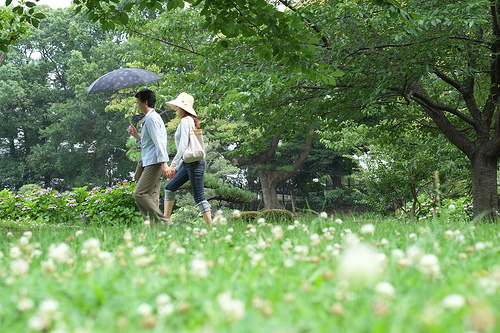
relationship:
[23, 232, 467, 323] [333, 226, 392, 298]
grass has flowers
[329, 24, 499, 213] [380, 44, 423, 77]
tree has leaves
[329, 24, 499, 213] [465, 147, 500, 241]
tree has trunk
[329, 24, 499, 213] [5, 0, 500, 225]
tree in background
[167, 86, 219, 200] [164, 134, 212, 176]
woman has arm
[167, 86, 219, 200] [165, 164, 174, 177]
woman has hand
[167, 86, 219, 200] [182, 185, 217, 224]
woman has leg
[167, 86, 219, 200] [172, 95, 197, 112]
woman has hat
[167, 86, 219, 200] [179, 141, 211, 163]
woman carrying purse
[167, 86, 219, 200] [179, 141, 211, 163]
woman has purse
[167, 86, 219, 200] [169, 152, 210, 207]
woman has jeans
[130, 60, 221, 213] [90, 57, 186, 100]
people with umbrella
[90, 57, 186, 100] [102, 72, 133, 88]
umbrella has pattern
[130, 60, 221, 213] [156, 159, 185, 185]
people holding hands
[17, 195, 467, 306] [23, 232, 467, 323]
field has grass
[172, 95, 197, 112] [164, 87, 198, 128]
hat on head